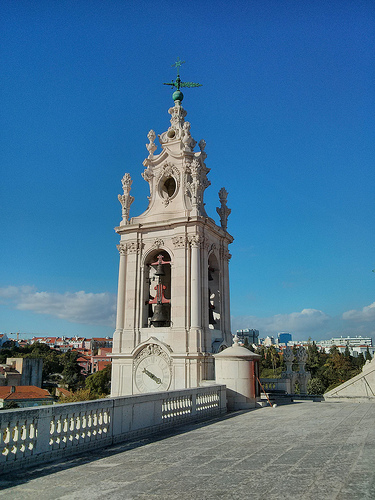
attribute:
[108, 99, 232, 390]
clock tower — tall, stone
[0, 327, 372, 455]
houses — many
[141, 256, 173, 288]
bell — small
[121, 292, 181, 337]
bell — big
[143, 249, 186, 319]
bell — large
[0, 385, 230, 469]
balustrade — concrete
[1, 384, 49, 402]
roof — red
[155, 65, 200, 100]
weather vane — green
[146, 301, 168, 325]
bell — large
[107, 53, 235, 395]
tower — ornate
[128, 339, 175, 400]
clock — round